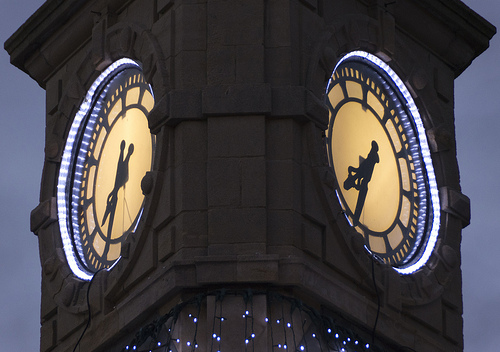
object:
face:
[324, 67, 419, 267]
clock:
[324, 48, 440, 275]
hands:
[343, 139, 379, 228]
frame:
[303, 12, 462, 308]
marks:
[333, 75, 387, 109]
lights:
[123, 309, 371, 351]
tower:
[3, 0, 496, 350]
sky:
[461, 115, 499, 259]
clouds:
[6, 93, 38, 183]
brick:
[168, 22, 303, 186]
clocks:
[57, 57, 158, 283]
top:
[4, 0, 496, 44]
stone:
[174, 181, 287, 253]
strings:
[218, 285, 320, 317]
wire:
[363, 253, 385, 345]